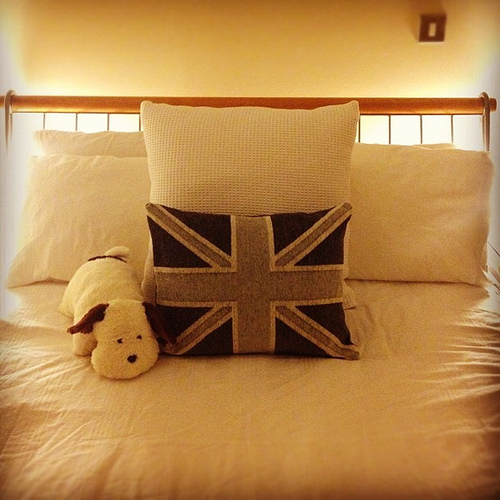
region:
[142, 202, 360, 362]
Britain's flag pattern on a pillow that is on the bed.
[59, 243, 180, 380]
Brown and white dog that is stuffed.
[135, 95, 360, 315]
Large white pillow behind an accent pillow.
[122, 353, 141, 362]
Little black nose on a stuffed dog.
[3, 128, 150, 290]
Two white pillows behind a stuffed dog.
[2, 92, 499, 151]
Brown head board behind the pillows.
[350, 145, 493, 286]
White pillow to the right of the Britain flag pillow.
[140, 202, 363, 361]
Accent pillow on a bed with Britains flag pattern.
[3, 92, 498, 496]
A bed with five white pillows and a brown head board.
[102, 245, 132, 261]
Little white tail on a dog.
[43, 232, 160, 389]
small stuffed animal dog on bed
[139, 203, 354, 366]
uk pillow on bed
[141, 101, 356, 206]
throw pillow on bed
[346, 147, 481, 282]
pillow at top of bed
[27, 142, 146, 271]
pillow at top of bed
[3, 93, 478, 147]
headboard at top of bed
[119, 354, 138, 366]
black nose of dog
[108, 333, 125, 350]
small eyes of dog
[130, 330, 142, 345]
small eyes of dog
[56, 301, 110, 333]
brown ear of dog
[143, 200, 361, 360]
small pillow with the British flag on it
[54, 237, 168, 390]
stuffed animal laying on the bed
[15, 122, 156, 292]
two white pillows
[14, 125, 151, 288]
pillow leaning on another pillow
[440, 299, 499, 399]
wrinkles in the sheets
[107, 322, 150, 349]
two small black eyes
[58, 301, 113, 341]
long brown ear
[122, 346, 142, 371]
small black button nose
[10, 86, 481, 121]
wooden rod on the top of the bedframe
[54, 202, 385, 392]
stuffed animal next to a pillow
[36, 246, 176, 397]
The stuffed animal is a dog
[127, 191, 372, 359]
Black and grey pillow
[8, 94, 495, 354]
Pillows on a bed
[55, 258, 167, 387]
The stuffed animal is white and brown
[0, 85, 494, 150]
The bed rail is brown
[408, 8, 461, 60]
Silver and white switch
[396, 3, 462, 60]
The switch is above the bed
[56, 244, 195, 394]
The stuffed animal is on the bed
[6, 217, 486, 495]
The comforter is white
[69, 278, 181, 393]
The stuffed animal has brown ears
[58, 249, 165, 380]
brown and white stuffed dog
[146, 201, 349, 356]
patterned pillow on bed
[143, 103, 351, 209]
checkered pillow on bed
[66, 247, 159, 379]
stuffed dog on bed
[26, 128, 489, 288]
white pillows on bed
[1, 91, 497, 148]
honey brown head board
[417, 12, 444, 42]
light switch on wall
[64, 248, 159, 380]
stuffed dog next to pillows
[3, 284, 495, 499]
white comforter on bed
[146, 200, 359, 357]
pillow next to stuffed dog